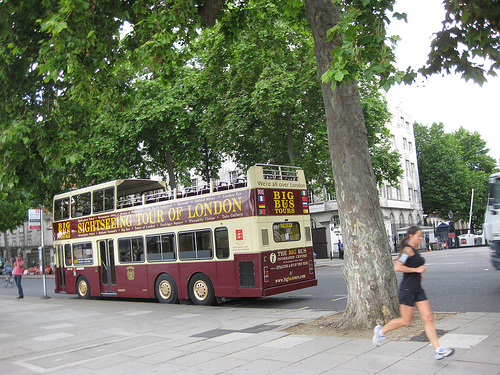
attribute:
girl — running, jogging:
[373, 226, 453, 360]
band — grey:
[398, 250, 409, 264]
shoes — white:
[373, 324, 455, 361]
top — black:
[403, 245, 425, 290]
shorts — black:
[399, 283, 428, 309]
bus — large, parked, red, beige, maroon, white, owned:
[53, 166, 317, 306]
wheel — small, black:
[189, 275, 214, 304]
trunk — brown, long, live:
[306, 0, 411, 325]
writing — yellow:
[53, 191, 296, 238]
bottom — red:
[57, 264, 316, 295]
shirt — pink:
[12, 260, 24, 275]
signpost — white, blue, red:
[30, 210, 47, 296]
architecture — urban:
[4, 101, 430, 266]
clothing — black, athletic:
[397, 245, 428, 305]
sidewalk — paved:
[2, 298, 498, 374]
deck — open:
[53, 172, 305, 220]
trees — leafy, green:
[1, 2, 409, 323]